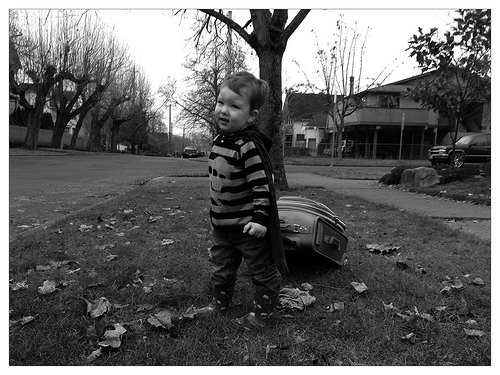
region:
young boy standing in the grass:
[188, 73, 304, 335]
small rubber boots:
[178, 273, 293, 340]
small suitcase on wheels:
[270, 188, 366, 275]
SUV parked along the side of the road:
[423, 120, 493, 181]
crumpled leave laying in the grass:
[86, 296, 113, 320]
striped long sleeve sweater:
[188, 135, 276, 225]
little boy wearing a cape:
[189, 71, 302, 335]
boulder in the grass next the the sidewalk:
[392, 164, 440, 191]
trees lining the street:
[13, 13, 173, 156]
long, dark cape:
[243, 133, 305, 281]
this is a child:
[185, 64, 286, 329]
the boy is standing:
[200, 70, 283, 329]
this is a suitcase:
[280, 182, 348, 271]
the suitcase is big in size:
[282, 189, 337, 270]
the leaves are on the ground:
[63, 245, 185, 355]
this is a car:
[427, 130, 484, 162]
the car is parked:
[427, 131, 489, 166]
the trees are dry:
[32, 56, 132, 145]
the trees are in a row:
[0, 52, 137, 128]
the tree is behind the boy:
[252, 14, 299, 57]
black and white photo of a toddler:
[190, 66, 289, 308]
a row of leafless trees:
[17, 31, 138, 148]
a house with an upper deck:
[339, 78, 433, 157]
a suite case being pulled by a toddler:
[275, 188, 351, 275]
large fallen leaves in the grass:
[86, 231, 166, 353]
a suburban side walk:
[332, 166, 472, 233]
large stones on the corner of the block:
[384, 158, 436, 195]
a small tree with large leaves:
[408, 19, 488, 149]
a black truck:
[425, 127, 485, 174]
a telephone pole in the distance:
[157, 83, 184, 159]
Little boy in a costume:
[168, 61, 365, 341]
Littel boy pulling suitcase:
[165, 62, 381, 302]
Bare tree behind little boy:
[167, 7, 357, 285]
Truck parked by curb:
[421, 124, 486, 171]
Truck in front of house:
[322, 61, 498, 197]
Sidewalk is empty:
[291, 160, 498, 257]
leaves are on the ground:
[80, 168, 488, 357]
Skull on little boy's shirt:
[187, 121, 282, 251]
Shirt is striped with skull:
[186, 135, 316, 266]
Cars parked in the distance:
[176, 136, 207, 174]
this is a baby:
[197, 66, 292, 286]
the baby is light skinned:
[226, 110, 241, 115]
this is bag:
[291, 195, 333, 255]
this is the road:
[41, 150, 93, 183]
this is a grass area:
[99, 231, 168, 305]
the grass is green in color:
[376, 270, 416, 289]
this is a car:
[438, 130, 491, 154]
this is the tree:
[409, 37, 467, 120]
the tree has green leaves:
[427, 78, 452, 96]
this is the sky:
[123, 26, 165, 51]